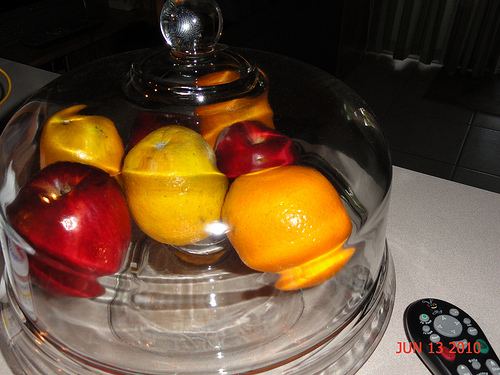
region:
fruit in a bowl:
[246, 166, 331, 251]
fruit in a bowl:
[145, 135, 215, 230]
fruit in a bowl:
[35, 161, 120, 251]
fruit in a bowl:
[65, 100, 110, 160]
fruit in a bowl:
[220, 125, 270, 155]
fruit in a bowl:
[225, 75, 275, 110]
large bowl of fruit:
[125, 45, 376, 370]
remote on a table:
[401, 276, 486, 371]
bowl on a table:
[241, 46, 391, 348]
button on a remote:
[427, 311, 471, 334]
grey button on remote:
[418, 313, 433, 324]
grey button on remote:
[420, 323, 430, 334]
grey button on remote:
[427, 330, 440, 345]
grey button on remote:
[448, 305, 461, 317]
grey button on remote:
[463, 313, 473, 326]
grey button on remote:
[466, 325, 476, 335]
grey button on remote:
[468, 359, 478, 369]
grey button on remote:
[458, 359, 466, 374]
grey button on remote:
[485, 355, 499, 371]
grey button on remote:
[430, 310, 461, 336]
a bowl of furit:
[39, 114, 299, 314]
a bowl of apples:
[42, 93, 359, 293]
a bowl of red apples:
[43, 63, 426, 365]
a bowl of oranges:
[78, 58, 378, 318]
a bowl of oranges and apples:
[108, 113, 350, 350]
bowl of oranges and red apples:
[14, 91, 351, 343]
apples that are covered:
[76, 116, 382, 276]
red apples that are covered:
[29, 78, 486, 364]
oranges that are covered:
[71, 43, 418, 372]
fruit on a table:
[54, 43, 391, 288]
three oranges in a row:
[42, 108, 354, 291]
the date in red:
[394, 342, 484, 354]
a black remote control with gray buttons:
[404, 297, 498, 373]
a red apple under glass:
[12, 161, 132, 296]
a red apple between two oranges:
[213, 122, 293, 174]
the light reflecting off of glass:
[204, 219, 231, 236]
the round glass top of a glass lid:
[158, 1, 225, 56]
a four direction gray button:
[434, 314, 462, 336]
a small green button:
[420, 314, 428, 321]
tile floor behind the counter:
[368, 88, 497, 192]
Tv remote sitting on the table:
[402, 296, 497, 372]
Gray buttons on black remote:
[416, 305, 499, 374]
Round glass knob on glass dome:
[160, 1, 220, 47]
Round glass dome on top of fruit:
[1, 1, 397, 370]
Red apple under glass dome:
[6, 157, 131, 297]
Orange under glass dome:
[221, 151, 361, 286]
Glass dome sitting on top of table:
[3, 2, 394, 372]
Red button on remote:
[440, 345, 454, 358]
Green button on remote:
[475, 337, 487, 352]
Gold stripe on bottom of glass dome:
[1, 238, 388, 374]